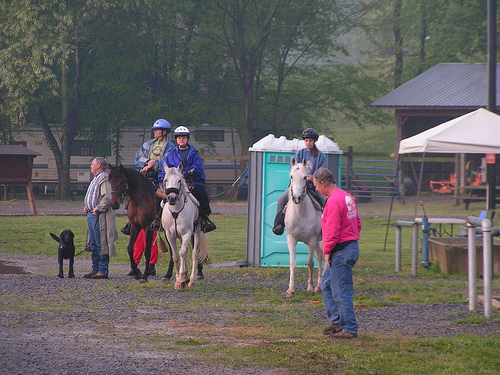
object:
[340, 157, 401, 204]
fence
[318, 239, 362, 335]
jeans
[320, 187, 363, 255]
shirt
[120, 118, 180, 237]
rider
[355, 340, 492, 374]
grass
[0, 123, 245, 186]
wall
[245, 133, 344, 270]
bottle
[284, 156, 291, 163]
dot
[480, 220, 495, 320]
poles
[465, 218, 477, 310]
poles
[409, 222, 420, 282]
poles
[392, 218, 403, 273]
poles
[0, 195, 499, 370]
ground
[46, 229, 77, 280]
dog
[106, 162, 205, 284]
horse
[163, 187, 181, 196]
fabric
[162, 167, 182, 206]
horse's face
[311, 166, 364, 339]
man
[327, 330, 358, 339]
shoe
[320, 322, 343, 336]
shoe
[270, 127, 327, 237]
girl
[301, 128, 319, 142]
helmet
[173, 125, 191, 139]
helmet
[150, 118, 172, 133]
helmet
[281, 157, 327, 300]
white horse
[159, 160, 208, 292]
white horse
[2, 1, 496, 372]
park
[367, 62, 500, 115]
roof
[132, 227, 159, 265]
fabric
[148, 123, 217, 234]
woman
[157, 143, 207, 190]
jacket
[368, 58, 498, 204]
building